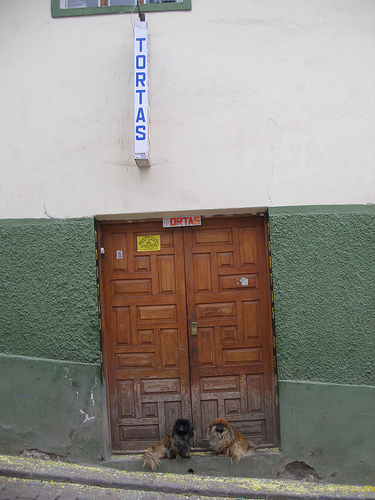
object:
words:
[134, 36, 146, 55]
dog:
[209, 416, 251, 464]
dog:
[139, 418, 195, 472]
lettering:
[169, 217, 176, 226]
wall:
[0, 0, 374, 463]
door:
[97, 215, 193, 457]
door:
[181, 213, 281, 450]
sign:
[135, 35, 152, 176]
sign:
[162, 214, 202, 228]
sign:
[136, 234, 163, 252]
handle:
[191, 319, 198, 337]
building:
[0, 1, 375, 469]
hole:
[281, 458, 321, 484]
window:
[49, 0, 194, 17]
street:
[0, 453, 374, 499]